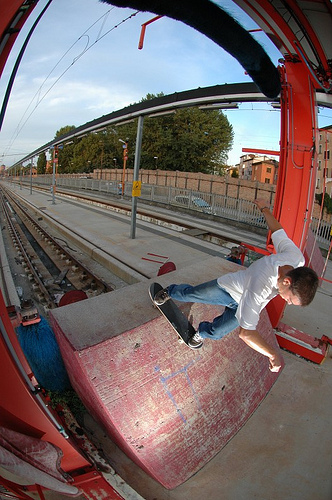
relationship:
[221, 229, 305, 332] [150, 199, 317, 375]
shirt on boy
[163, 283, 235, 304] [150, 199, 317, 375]
jean on boy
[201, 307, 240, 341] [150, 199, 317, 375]
jean on boy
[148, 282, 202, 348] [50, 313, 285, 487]
skateboard on ramp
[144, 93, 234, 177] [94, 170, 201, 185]
tree behind fence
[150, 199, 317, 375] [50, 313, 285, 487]
boy on ramp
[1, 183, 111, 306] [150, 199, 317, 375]
tracks behind boy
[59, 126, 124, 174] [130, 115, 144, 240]
tree behind post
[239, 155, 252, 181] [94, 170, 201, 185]
building behind fence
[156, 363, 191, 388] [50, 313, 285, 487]
mark on ramp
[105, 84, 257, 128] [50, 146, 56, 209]
rail on pole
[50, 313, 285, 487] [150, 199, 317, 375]
ramp under boy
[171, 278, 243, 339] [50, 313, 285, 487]
jeans on ramp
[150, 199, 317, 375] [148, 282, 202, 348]
boy on skateboard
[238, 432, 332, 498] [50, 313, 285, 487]
floor below ramp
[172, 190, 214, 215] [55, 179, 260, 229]
car behind fence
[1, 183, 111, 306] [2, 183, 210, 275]
tracks along walkway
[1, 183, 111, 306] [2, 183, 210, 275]
tracks near walkway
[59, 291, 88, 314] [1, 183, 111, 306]
block on tracks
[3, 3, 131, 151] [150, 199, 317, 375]
wires over boy